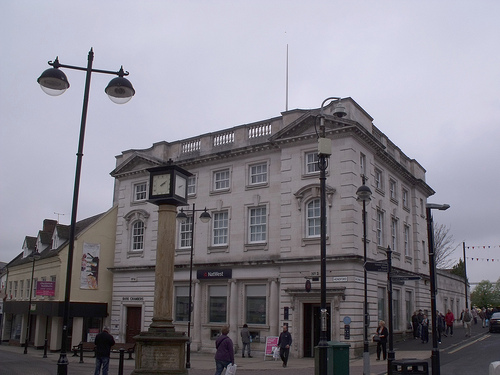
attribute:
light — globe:
[37, 67, 70, 98]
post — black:
[56, 48, 95, 374]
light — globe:
[103, 76, 136, 105]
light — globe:
[176, 212, 188, 226]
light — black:
[331, 101, 350, 121]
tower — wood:
[129, 205, 192, 374]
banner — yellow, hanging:
[78, 241, 103, 289]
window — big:
[129, 216, 146, 253]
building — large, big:
[106, 96, 435, 360]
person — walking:
[278, 323, 293, 368]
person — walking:
[374, 321, 389, 363]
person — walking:
[215, 326, 239, 374]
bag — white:
[226, 363, 238, 375]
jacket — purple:
[215, 334, 237, 367]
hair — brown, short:
[221, 323, 231, 335]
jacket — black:
[276, 330, 293, 350]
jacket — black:
[93, 331, 116, 358]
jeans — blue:
[215, 359, 236, 374]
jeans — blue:
[94, 354, 110, 374]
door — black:
[310, 305, 330, 357]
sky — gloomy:
[1, 1, 500, 306]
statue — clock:
[129, 156, 194, 374]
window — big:
[305, 196, 329, 239]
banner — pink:
[36, 280, 58, 297]